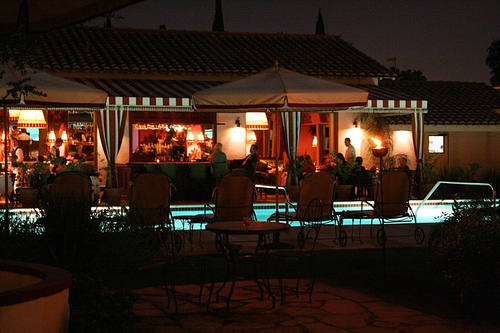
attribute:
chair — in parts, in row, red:
[124, 170, 182, 221]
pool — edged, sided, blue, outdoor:
[410, 187, 484, 224]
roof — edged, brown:
[37, 28, 394, 81]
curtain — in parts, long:
[96, 104, 130, 186]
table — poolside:
[209, 215, 294, 310]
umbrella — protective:
[184, 56, 372, 125]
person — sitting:
[244, 143, 265, 173]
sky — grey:
[352, 0, 490, 60]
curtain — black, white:
[408, 110, 431, 161]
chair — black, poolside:
[348, 167, 428, 240]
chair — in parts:
[284, 165, 352, 241]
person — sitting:
[351, 156, 376, 182]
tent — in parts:
[85, 78, 190, 106]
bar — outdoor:
[126, 125, 220, 170]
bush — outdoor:
[444, 206, 499, 284]